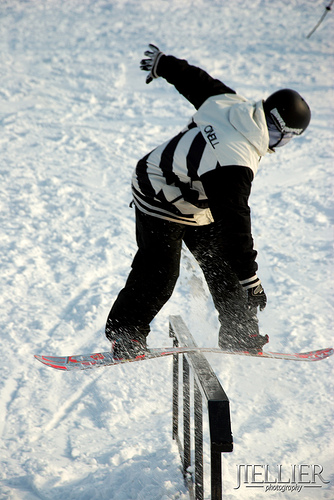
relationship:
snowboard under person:
[29, 342, 333, 371] [100, 42, 313, 358]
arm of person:
[158, 51, 233, 104] [100, 42, 313, 358]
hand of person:
[138, 41, 166, 85] [100, 42, 313, 358]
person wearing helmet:
[100, 42, 313, 358] [263, 89, 312, 149]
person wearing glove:
[100, 42, 313, 358] [243, 278, 270, 312]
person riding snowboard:
[100, 42, 313, 358] [29, 342, 333, 371]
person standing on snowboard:
[100, 42, 313, 358] [29, 342, 333, 371]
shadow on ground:
[23, 445, 184, 499] [4, 366, 188, 498]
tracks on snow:
[3, 261, 111, 428] [2, 3, 331, 498]